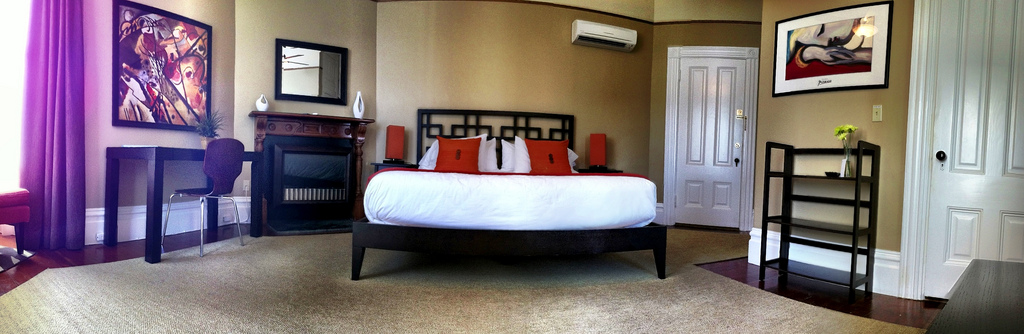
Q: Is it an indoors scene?
A: Yes, it is indoors.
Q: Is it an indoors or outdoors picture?
A: It is indoors.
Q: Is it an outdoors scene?
A: No, it is indoors.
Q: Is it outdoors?
A: No, it is indoors.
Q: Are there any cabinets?
A: No, there are no cabinets.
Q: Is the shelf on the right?
A: Yes, the shelf is on the right of the image.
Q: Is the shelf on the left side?
A: No, the shelf is on the right of the image.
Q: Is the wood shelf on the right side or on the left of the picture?
A: The shelf is on the right of the image.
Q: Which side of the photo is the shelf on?
A: The shelf is on the right of the image.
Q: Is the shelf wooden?
A: Yes, the shelf is wooden.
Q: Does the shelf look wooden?
A: Yes, the shelf is wooden.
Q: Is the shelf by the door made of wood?
A: Yes, the shelf is made of wood.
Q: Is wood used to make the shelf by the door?
A: Yes, the shelf is made of wood.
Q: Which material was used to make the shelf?
A: The shelf is made of wood.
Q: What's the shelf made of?
A: The shelf is made of wood.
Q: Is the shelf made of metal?
A: No, the shelf is made of wood.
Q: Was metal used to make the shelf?
A: No, the shelf is made of wood.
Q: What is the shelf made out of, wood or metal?
A: The shelf is made of wood.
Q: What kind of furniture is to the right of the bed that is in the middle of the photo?
A: The piece of furniture is a shelf.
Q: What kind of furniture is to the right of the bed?
A: The piece of furniture is a shelf.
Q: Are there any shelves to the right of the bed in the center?
A: Yes, there is a shelf to the right of the bed.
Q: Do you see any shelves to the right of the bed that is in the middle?
A: Yes, there is a shelf to the right of the bed.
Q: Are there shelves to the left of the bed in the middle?
A: No, the shelf is to the right of the bed.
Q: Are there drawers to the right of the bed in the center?
A: No, there is a shelf to the right of the bed.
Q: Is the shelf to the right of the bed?
A: Yes, the shelf is to the right of the bed.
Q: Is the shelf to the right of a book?
A: No, the shelf is to the right of the bed.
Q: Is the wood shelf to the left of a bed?
A: No, the shelf is to the right of a bed.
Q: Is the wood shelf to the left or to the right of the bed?
A: The shelf is to the right of the bed.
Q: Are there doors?
A: Yes, there is a door.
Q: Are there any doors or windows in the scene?
A: Yes, there is a door.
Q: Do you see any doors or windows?
A: Yes, there is a door.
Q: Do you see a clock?
A: No, there are no clocks.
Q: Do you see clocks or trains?
A: No, there are no clocks or trains.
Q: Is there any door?
A: Yes, there is a door.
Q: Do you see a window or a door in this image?
A: Yes, there is a door.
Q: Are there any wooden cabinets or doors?
A: Yes, there is a wood door.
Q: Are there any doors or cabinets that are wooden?
A: Yes, the door is wooden.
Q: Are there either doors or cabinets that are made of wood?
A: Yes, the door is made of wood.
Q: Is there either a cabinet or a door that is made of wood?
A: Yes, the door is made of wood.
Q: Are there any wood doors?
A: Yes, there is a wood door.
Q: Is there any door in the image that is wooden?
A: Yes, there is a door that is wooden.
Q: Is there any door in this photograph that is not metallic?
A: Yes, there is a wooden door.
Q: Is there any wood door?
A: Yes, there is a door that is made of wood.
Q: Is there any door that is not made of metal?
A: Yes, there is a door that is made of wood.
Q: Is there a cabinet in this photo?
A: No, there are no cabinets.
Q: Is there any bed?
A: Yes, there is a bed.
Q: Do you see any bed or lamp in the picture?
A: Yes, there is a bed.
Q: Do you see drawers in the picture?
A: No, there are no drawers.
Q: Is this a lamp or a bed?
A: This is a bed.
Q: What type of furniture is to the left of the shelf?
A: The piece of furniture is a bed.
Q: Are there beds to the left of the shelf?
A: Yes, there is a bed to the left of the shelf.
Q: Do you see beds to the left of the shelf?
A: Yes, there is a bed to the left of the shelf.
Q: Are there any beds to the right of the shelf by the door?
A: No, the bed is to the left of the shelf.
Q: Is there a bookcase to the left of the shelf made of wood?
A: No, there is a bed to the left of the shelf.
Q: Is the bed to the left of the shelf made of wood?
A: Yes, the bed is to the left of the shelf.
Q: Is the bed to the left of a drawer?
A: No, the bed is to the left of the shelf.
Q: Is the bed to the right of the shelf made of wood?
A: No, the bed is to the left of the shelf.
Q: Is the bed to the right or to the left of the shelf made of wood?
A: The bed is to the left of the shelf.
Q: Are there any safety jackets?
A: No, there are no safety jackets.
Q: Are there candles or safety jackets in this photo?
A: No, there are no safety jackets or candles.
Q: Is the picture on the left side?
A: Yes, the picture is on the left of the image.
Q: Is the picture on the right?
A: No, the picture is on the left of the image.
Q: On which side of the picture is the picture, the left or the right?
A: The picture is on the left of the image.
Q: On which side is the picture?
A: The picture is on the left of the image.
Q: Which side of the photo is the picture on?
A: The picture is on the left of the image.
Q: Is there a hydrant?
A: No, there are no fire hydrants.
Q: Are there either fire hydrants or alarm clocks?
A: No, there are no fire hydrants or alarm clocks.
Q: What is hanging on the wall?
A: The artwork is hanging on the wall.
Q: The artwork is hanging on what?
A: The artwork is hanging on the wall.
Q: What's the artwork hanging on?
A: The artwork is hanging on the wall.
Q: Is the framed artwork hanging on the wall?
A: Yes, the artwork is hanging on the wall.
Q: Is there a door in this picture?
A: Yes, there are doors.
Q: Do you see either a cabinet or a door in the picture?
A: Yes, there are doors.